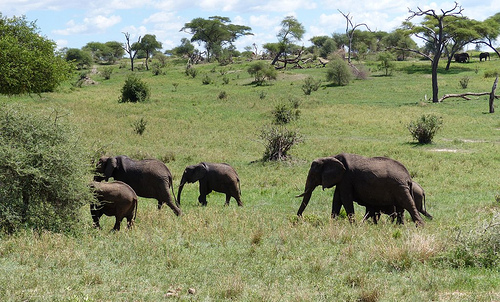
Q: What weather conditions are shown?
A: It is cloudy.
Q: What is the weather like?
A: It is cloudy.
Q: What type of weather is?
A: It is cloudy.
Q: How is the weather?
A: It is cloudy.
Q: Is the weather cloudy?
A: Yes, it is cloudy.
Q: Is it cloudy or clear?
A: It is cloudy.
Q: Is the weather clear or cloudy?
A: It is cloudy.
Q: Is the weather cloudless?
A: No, it is cloudy.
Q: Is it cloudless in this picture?
A: No, it is cloudy.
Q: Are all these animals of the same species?
A: Yes, all the animals are elephants.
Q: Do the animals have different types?
A: No, all the animals are elephants.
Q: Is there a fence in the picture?
A: No, there are no fences.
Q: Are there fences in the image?
A: No, there are no fences.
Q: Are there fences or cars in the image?
A: No, there are no fences or cars.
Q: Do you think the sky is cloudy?
A: Yes, the sky is cloudy.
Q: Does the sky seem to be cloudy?
A: Yes, the sky is cloudy.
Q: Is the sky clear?
A: No, the sky is cloudy.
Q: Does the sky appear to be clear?
A: No, the sky is cloudy.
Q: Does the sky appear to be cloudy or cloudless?
A: The sky is cloudy.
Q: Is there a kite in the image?
A: No, there are no kites.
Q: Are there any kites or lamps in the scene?
A: No, there are no kites or lamps.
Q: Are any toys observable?
A: No, there are no toys.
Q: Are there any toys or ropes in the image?
A: No, there are no toys or ropes.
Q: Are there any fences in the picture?
A: No, there are no fences.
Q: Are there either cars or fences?
A: No, there are no fences or cars.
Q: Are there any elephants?
A: Yes, there is an elephant.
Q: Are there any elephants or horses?
A: Yes, there is an elephant.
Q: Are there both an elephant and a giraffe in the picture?
A: No, there is an elephant but no giraffes.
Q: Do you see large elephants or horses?
A: Yes, there is a large elephant.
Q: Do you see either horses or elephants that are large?
A: Yes, the elephant is large.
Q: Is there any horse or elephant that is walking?
A: Yes, the elephant is walking.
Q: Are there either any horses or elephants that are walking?
A: Yes, the elephant is walking.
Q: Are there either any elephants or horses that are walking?
A: Yes, the elephant is walking.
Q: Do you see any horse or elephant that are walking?
A: Yes, the elephant is walking.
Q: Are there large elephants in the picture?
A: Yes, there is a large elephant.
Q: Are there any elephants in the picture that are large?
A: Yes, there is an elephant that is large.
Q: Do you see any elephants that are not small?
A: Yes, there is a large elephant.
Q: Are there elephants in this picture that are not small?
A: Yes, there is a large elephant.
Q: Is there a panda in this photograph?
A: No, there are no pandas.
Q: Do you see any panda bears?
A: No, there are no panda bears.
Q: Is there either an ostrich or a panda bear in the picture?
A: No, there are no pandas or ostriches.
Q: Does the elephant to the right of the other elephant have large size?
A: Yes, the elephant is large.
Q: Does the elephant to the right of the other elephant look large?
A: Yes, the elephant is large.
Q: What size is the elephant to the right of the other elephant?
A: The elephant is large.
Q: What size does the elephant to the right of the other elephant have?
A: The elephant has large size.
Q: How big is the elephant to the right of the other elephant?
A: The elephant is large.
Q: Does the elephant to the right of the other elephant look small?
A: No, the elephant is large.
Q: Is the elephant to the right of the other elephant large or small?
A: The elephant is large.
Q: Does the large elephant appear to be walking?
A: Yes, the elephant is walking.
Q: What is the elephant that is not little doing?
A: The elephant is walking.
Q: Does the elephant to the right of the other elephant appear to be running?
A: No, the elephant is walking.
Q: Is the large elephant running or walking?
A: The elephant is walking.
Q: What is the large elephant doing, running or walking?
A: The elephant is walking.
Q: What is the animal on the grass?
A: The animal is an elephant.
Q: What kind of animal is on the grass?
A: The animal is an elephant.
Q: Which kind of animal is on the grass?
A: The animal is an elephant.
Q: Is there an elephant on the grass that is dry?
A: Yes, there is an elephant on the grass.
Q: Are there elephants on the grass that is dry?
A: Yes, there is an elephant on the grass.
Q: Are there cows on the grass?
A: No, there is an elephant on the grass.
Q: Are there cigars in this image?
A: No, there are no cigars.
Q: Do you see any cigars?
A: No, there are no cigars.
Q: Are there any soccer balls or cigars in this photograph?
A: No, there are no cigars or soccer balls.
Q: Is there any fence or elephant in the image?
A: Yes, there are elephants.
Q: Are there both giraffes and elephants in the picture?
A: No, there are elephants but no giraffes.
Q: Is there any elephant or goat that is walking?
A: Yes, the elephants are walking.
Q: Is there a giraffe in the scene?
A: No, there are no giraffes.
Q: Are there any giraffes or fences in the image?
A: No, there are no giraffes or fences.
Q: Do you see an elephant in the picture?
A: Yes, there is an elephant.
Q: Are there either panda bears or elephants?
A: Yes, there is an elephant.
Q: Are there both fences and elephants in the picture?
A: No, there is an elephant but no fences.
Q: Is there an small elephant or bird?
A: Yes, there is a small elephant.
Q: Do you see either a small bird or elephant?
A: Yes, there is a small elephant.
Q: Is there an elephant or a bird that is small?
A: Yes, the elephant is small.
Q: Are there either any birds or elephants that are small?
A: Yes, the elephant is small.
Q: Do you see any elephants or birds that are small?
A: Yes, the elephant is small.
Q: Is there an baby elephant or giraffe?
A: Yes, there is a baby elephant.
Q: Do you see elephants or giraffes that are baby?
A: Yes, the elephant is a baby.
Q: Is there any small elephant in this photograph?
A: Yes, there is a small elephant.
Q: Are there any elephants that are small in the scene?
A: Yes, there is a small elephant.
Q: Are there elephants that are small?
A: Yes, there is an elephant that is small.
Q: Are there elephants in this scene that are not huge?
A: Yes, there is a small elephant.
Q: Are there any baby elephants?
A: Yes, there is a baby elephant.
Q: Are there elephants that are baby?
A: Yes, there is an elephant that is a baby.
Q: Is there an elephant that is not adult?
A: Yes, there is an baby elephant.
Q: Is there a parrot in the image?
A: No, there are no parrots.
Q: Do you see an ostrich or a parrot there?
A: No, there are no parrots or ostriches.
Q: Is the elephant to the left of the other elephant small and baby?
A: Yes, the elephant is small and baby.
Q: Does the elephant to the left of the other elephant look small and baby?
A: Yes, the elephant is small and baby.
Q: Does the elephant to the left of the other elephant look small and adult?
A: No, the elephant is small but baby.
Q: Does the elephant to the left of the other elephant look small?
A: Yes, the elephant is small.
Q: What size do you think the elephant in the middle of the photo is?
A: The elephant is small.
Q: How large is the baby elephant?
A: The elephant is small.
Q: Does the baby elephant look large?
A: No, the elephant is small.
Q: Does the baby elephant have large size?
A: No, the elephant is small.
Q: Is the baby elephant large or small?
A: The elephant is small.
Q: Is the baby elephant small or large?
A: The elephant is small.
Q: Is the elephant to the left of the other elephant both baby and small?
A: Yes, the elephant is a baby and small.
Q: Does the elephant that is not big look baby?
A: Yes, the elephant is a baby.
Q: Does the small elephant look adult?
A: No, the elephant is a baby.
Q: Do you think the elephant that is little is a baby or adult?
A: The elephant is a baby.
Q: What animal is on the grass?
A: The animal is an elephant.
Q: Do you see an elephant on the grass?
A: Yes, there is an elephant on the grass.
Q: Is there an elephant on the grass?
A: Yes, there is an elephant on the grass.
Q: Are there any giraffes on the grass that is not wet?
A: No, there is an elephant on the grass.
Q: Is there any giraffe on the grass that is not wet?
A: No, there is an elephant on the grass.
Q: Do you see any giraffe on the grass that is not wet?
A: No, there is an elephant on the grass.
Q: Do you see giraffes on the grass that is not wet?
A: No, there is an elephant on the grass.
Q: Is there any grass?
A: Yes, there is grass.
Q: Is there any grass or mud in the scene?
A: Yes, there is grass.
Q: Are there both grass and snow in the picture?
A: No, there is grass but no snow.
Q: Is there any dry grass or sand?
A: Yes, there is dry grass.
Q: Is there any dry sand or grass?
A: Yes, there is dry grass.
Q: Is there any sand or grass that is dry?
A: Yes, the grass is dry.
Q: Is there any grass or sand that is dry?
A: Yes, the grass is dry.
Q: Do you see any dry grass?
A: Yes, there is dry grass.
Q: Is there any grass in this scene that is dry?
A: Yes, there is dry grass.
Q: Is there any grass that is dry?
A: Yes, there is grass that is dry.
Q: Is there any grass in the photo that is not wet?
A: Yes, there is dry grass.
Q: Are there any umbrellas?
A: No, there are no umbrellas.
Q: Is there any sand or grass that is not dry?
A: No, there is grass but it is dry.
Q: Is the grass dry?
A: Yes, the grass is dry.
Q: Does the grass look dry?
A: Yes, the grass is dry.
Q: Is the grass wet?
A: No, the grass is dry.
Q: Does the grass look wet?
A: No, the grass is dry.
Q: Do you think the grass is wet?
A: No, the grass is dry.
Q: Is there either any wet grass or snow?
A: No, there is grass but it is dry.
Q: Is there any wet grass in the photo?
A: No, there is grass but it is dry.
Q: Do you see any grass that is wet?
A: No, there is grass but it is dry.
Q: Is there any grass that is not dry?
A: No, there is grass but it is dry.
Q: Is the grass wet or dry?
A: The grass is dry.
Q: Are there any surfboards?
A: No, there are no surfboards.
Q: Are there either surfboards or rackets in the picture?
A: No, there are no surfboards or rackets.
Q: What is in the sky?
A: The clouds are in the sky.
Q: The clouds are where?
A: The clouds are in the sky.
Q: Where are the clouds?
A: The clouds are in the sky.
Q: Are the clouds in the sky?
A: Yes, the clouds are in the sky.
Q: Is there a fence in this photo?
A: No, there are no fences.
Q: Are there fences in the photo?
A: No, there are no fences.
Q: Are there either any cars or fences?
A: No, there are no fences or cars.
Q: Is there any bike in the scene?
A: No, there are no bikes.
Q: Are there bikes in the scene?
A: No, there are no bikes.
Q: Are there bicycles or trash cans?
A: No, there are no bicycles or trash cans.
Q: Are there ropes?
A: No, there are no ropes.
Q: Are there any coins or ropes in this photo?
A: No, there are no ropes or coins.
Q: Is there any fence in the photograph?
A: No, there are no fences.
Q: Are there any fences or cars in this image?
A: No, there are no fences or cars.